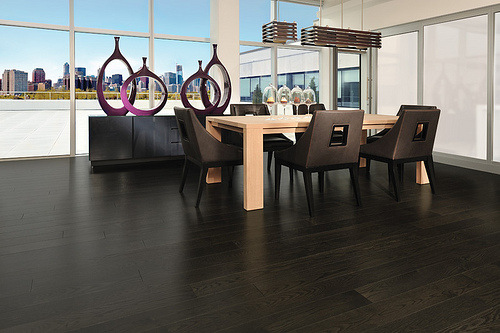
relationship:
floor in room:
[3, 152, 500, 332] [2, 1, 498, 331]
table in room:
[203, 113, 435, 212] [2, 1, 498, 331]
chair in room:
[270, 106, 367, 221] [2, 1, 498, 331]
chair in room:
[358, 105, 438, 205] [2, 1, 498, 331]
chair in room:
[171, 104, 251, 213] [2, 1, 498, 331]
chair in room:
[231, 100, 297, 192] [2, 1, 498, 331]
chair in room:
[369, 105, 439, 182] [2, 1, 498, 331]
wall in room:
[326, 5, 499, 177] [2, 1, 498, 331]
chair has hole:
[270, 106, 367, 221] [327, 124, 350, 150]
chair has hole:
[358, 105, 438, 205] [411, 120, 430, 143]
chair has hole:
[171, 104, 251, 213] [178, 119, 192, 143]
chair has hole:
[231, 100, 297, 192] [245, 110, 257, 116]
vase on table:
[95, 35, 140, 117] [85, 113, 247, 174]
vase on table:
[119, 55, 171, 115] [85, 113, 247, 174]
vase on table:
[182, 58, 223, 113] [85, 113, 247, 174]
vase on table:
[201, 44, 234, 115] [85, 113, 247, 174]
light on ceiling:
[262, 21, 299, 46] [290, 1, 387, 9]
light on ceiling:
[300, 23, 383, 53] [290, 1, 387, 9]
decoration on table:
[261, 81, 279, 116] [203, 113, 435, 212]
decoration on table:
[276, 82, 293, 117] [203, 113, 435, 212]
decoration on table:
[291, 81, 305, 117] [203, 113, 435, 212]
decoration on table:
[301, 85, 317, 115] [203, 113, 435, 212]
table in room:
[85, 113, 247, 174] [2, 1, 498, 331]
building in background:
[1, 67, 31, 95] [2, 55, 218, 98]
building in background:
[33, 66, 46, 91] [2, 55, 218, 98]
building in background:
[63, 60, 71, 89] [2, 55, 218, 98]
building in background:
[175, 62, 185, 92] [2, 55, 218, 98]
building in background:
[165, 72, 180, 95] [2, 55, 218, 98]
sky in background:
[1, 2, 320, 92] [2, 55, 218, 98]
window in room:
[151, 38, 215, 98] [2, 1, 498, 331]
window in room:
[74, 31, 152, 100] [2, 1, 498, 331]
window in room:
[2, 23, 73, 106] [2, 1, 498, 331]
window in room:
[151, 0, 218, 40] [2, 1, 498, 331]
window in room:
[73, 1, 153, 38] [2, 1, 498, 331]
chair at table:
[270, 106, 367, 221] [203, 113, 435, 212]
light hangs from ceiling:
[262, 21, 299, 46] [290, 1, 387, 9]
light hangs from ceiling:
[300, 23, 383, 53] [290, 1, 387, 9]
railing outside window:
[2, 87, 212, 97] [74, 31, 152, 100]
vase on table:
[182, 58, 223, 113] [203, 113, 435, 212]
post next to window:
[69, 31, 77, 102] [74, 31, 152, 100]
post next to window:
[69, 31, 77, 102] [2, 23, 73, 106]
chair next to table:
[270, 106, 367, 221] [203, 113, 435, 212]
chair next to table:
[369, 105, 439, 182] [203, 113, 435, 212]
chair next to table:
[358, 105, 438, 205] [203, 113, 435, 212]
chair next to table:
[231, 100, 297, 192] [203, 113, 435, 212]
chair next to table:
[171, 104, 251, 213] [203, 113, 435, 212]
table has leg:
[203, 113, 435, 212] [240, 125, 266, 212]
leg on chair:
[194, 164, 212, 210] [171, 104, 251, 213]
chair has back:
[270, 106, 367, 221] [303, 109, 366, 167]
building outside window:
[63, 60, 71, 89] [2, 23, 73, 106]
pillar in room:
[208, 2, 241, 116] [2, 1, 498, 331]